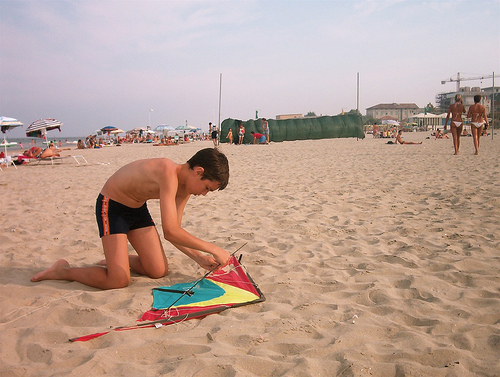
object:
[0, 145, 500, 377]
beach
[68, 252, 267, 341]
kite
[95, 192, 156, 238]
shorts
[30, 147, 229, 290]
boy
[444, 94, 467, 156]
ladies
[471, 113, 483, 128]
bikinis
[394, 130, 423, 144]
man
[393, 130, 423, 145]
bathing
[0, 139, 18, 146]
boat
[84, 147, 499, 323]
ground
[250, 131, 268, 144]
man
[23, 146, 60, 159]
lady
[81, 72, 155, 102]
sun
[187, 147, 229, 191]
hair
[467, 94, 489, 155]
women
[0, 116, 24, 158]
umbrella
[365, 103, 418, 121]
building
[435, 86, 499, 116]
building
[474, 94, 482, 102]
hair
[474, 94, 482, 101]
brown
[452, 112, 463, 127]
bikini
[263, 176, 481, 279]
sand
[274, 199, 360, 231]
divets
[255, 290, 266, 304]
top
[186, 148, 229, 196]
head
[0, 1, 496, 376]
background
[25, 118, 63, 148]
unbrella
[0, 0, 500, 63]
sky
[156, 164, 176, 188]
skin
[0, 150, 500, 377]
place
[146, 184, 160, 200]
chest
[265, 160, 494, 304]
footsteps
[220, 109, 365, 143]
tent